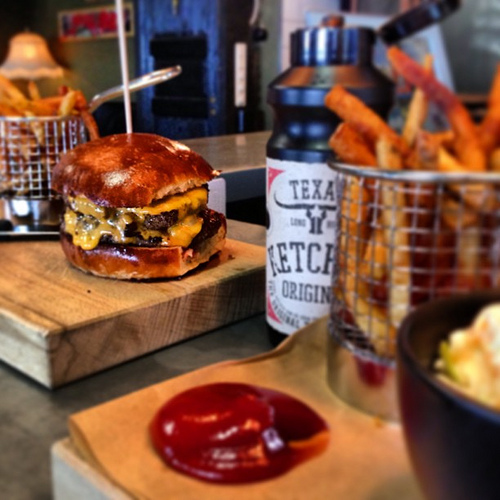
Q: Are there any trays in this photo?
A: No, there are no trays.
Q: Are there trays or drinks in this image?
A: No, there are no trays or drinks.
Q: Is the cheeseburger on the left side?
A: Yes, the cheeseburger is on the left of the image.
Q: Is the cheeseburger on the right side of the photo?
A: No, the cheeseburger is on the left of the image.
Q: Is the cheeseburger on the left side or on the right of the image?
A: The cheeseburger is on the left of the image.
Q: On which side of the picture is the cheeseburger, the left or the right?
A: The cheeseburger is on the left of the image.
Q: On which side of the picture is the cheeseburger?
A: The cheeseburger is on the left of the image.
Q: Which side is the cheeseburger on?
A: The cheeseburger is on the left of the image.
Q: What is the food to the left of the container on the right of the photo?
A: The food is a cheeseburger.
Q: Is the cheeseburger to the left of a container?
A: Yes, the cheeseburger is to the left of a container.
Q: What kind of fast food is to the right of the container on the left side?
A: The food is a cheeseburger.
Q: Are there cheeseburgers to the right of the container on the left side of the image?
A: Yes, there is a cheeseburger to the right of the container.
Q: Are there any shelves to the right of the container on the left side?
A: No, there is a cheeseburger to the right of the container.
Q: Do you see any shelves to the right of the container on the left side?
A: No, there is a cheeseburger to the right of the container.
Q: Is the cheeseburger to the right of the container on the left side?
A: Yes, the cheeseburger is to the right of the container.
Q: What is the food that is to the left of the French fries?
A: The food is a cheeseburger.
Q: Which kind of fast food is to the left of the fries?
A: The food is a cheeseburger.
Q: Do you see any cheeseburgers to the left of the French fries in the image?
A: Yes, there is a cheeseburger to the left of the French fries.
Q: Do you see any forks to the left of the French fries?
A: No, there is a cheeseburger to the left of the French fries.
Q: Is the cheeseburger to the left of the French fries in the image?
A: Yes, the cheeseburger is to the left of the French fries.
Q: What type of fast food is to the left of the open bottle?
A: The food is a cheeseburger.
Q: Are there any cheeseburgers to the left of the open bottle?
A: Yes, there is a cheeseburger to the left of the bottle.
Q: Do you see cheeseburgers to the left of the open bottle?
A: Yes, there is a cheeseburger to the left of the bottle.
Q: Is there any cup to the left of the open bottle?
A: No, there is a cheeseburger to the left of the bottle.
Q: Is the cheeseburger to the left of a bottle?
A: Yes, the cheeseburger is to the left of a bottle.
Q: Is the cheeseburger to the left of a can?
A: No, the cheeseburger is to the left of a bottle.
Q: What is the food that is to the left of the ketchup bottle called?
A: The food is a cheeseburger.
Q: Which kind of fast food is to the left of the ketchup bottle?
A: The food is a cheeseburger.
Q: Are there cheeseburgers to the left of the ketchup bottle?
A: Yes, there is a cheeseburger to the left of the ketchup bottle.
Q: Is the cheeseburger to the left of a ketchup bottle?
A: Yes, the cheeseburger is to the left of a ketchup bottle.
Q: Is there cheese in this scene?
A: Yes, there is cheese.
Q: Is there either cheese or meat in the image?
A: Yes, there is cheese.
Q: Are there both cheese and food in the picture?
A: Yes, there are both cheese and food.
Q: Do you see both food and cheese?
A: Yes, there are both cheese and food.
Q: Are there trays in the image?
A: No, there are no trays.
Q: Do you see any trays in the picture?
A: No, there are no trays.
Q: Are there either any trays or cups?
A: No, there are no trays or cups.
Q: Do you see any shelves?
A: No, there are no shelves.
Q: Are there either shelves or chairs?
A: No, there are no shelves or chairs.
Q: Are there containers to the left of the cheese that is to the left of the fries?
A: Yes, there is a container to the left of the cheese.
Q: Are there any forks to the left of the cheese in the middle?
A: No, there is a container to the left of the cheese.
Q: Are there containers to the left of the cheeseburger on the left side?
A: Yes, there is a container to the left of the cheeseburger.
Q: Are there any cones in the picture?
A: No, there are no cones.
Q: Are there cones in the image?
A: No, there are no cones.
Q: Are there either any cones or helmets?
A: No, there are no cones or helmets.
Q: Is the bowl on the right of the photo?
A: Yes, the bowl is on the right of the image.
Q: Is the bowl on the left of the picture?
A: No, the bowl is on the right of the image.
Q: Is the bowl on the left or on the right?
A: The bowl is on the right of the image.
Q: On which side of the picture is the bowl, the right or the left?
A: The bowl is on the right of the image.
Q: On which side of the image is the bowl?
A: The bowl is on the right of the image.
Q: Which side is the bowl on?
A: The bowl is on the right of the image.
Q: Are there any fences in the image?
A: No, there are no fences.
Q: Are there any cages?
A: No, there are no cages.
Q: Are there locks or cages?
A: No, there are no cages or locks.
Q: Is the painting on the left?
A: Yes, the painting is on the left of the image.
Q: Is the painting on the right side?
A: No, the painting is on the left of the image.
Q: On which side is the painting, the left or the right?
A: The painting is on the left of the image.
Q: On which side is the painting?
A: The painting is on the left of the image.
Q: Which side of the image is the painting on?
A: The painting is on the left of the image.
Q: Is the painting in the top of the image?
A: Yes, the painting is in the top of the image.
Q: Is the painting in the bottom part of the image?
A: No, the painting is in the top of the image.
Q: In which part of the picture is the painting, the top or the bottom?
A: The painting is in the top of the image.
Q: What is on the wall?
A: The painting is on the wall.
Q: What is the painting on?
A: The painting is on the wall.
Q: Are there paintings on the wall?
A: Yes, there is a painting on the wall.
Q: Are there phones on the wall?
A: No, there is a painting on the wall.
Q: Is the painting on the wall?
A: Yes, the painting is on the wall.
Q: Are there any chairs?
A: No, there are no chairs.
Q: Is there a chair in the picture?
A: No, there are no chairs.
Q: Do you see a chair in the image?
A: No, there are no chairs.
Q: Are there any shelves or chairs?
A: No, there are no chairs or shelves.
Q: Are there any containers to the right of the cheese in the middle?
A: Yes, there is a container to the right of the cheese.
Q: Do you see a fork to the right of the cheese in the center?
A: No, there is a container to the right of the cheese.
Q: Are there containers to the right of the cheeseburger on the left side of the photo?
A: Yes, there is a container to the right of the cheeseburger.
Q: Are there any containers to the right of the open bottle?
A: Yes, there is a container to the right of the bottle.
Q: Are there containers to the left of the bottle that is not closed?
A: No, the container is to the right of the bottle.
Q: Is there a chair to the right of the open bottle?
A: No, there is a container to the right of the bottle.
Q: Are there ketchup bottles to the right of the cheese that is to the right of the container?
A: Yes, there is a ketchup bottle to the right of the cheese.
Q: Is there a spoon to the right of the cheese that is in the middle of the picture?
A: No, there is a ketchup bottle to the right of the cheese.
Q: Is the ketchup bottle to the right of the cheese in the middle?
A: Yes, the ketchup bottle is to the right of the cheese.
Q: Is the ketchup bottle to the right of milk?
A: No, the ketchup bottle is to the right of the cheese.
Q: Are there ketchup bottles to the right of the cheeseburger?
A: Yes, there is a ketchup bottle to the right of the cheeseburger.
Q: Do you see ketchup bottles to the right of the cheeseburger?
A: Yes, there is a ketchup bottle to the right of the cheeseburger.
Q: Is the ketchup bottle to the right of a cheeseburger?
A: Yes, the ketchup bottle is to the right of a cheeseburger.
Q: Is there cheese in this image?
A: Yes, there is cheese.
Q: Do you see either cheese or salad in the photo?
A: Yes, there is cheese.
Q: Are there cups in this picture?
A: No, there are no cups.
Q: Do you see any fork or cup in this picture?
A: No, there are no cups or forks.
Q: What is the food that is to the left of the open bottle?
A: The food is cheese.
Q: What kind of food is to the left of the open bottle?
A: The food is cheese.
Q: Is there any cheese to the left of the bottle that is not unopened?
A: Yes, there is cheese to the left of the bottle.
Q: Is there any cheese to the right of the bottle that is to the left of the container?
A: No, the cheese is to the left of the bottle.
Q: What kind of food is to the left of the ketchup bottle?
A: The food is cheese.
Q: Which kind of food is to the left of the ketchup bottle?
A: The food is cheese.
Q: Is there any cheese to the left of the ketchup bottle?
A: Yes, there is cheese to the left of the ketchup bottle.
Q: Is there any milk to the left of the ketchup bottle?
A: No, there is cheese to the left of the ketchup bottle.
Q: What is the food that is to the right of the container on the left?
A: The food is cheese.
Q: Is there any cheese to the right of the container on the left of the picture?
A: Yes, there is cheese to the right of the container.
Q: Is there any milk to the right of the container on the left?
A: No, there is cheese to the right of the container.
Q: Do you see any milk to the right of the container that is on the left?
A: No, there is cheese to the right of the container.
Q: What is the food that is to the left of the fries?
A: The food is cheese.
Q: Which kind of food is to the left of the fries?
A: The food is cheese.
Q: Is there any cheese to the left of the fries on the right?
A: Yes, there is cheese to the left of the fries.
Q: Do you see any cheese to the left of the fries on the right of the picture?
A: Yes, there is cheese to the left of the fries.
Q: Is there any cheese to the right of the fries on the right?
A: No, the cheese is to the left of the French fries.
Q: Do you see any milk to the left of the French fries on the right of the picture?
A: No, there is cheese to the left of the French fries.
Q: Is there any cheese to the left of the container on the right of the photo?
A: Yes, there is cheese to the left of the container.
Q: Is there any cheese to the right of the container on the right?
A: No, the cheese is to the left of the container.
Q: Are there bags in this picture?
A: Yes, there is a bag.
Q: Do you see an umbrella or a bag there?
A: Yes, there is a bag.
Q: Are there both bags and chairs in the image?
A: No, there is a bag but no chairs.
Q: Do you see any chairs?
A: No, there are no chairs.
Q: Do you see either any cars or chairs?
A: No, there are no chairs or cars.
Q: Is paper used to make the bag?
A: Yes, the bag is made of paper.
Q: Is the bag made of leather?
A: No, the bag is made of paper.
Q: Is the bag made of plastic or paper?
A: The bag is made of paper.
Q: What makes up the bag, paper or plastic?
A: The bag is made of paper.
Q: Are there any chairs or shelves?
A: No, there are no chairs or shelves.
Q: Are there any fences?
A: No, there are no fences.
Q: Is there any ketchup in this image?
A: Yes, there is ketchup.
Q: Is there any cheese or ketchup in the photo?
A: Yes, there is ketchup.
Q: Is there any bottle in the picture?
A: Yes, there is a bottle.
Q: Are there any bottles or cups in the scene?
A: Yes, there is a bottle.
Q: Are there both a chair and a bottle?
A: No, there is a bottle but no chairs.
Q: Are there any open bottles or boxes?
A: Yes, there is an open bottle.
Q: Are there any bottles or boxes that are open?
A: Yes, the bottle is open.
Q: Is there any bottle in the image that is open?
A: Yes, there is an open bottle.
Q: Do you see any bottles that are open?
A: Yes, there is a bottle that is open.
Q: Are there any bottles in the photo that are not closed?
A: Yes, there is a open bottle.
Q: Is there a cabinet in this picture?
A: No, there are no cabinets.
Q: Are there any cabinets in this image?
A: No, there are no cabinets.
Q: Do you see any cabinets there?
A: No, there are no cabinets.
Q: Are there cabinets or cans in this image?
A: No, there are no cabinets or cans.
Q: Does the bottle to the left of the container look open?
A: Yes, the bottle is open.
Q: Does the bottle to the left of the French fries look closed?
A: No, the bottle is open.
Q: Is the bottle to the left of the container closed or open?
A: The bottle is open.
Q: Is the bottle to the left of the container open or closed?
A: The bottle is open.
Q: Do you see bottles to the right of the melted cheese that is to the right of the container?
A: Yes, there is a bottle to the right of the cheese.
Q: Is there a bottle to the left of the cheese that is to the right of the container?
A: No, the bottle is to the right of the cheese.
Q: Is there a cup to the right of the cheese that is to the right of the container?
A: No, there is a bottle to the right of the cheese.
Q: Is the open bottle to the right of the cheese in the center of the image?
A: Yes, the bottle is to the right of the cheese.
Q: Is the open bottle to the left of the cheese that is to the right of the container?
A: No, the bottle is to the right of the cheese.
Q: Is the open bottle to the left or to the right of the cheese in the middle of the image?
A: The bottle is to the right of the cheese.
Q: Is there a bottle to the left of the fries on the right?
A: Yes, there is a bottle to the left of the fries.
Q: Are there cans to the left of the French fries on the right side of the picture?
A: No, there is a bottle to the left of the fries.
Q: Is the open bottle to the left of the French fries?
A: Yes, the bottle is to the left of the French fries.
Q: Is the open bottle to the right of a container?
A: No, the bottle is to the left of a container.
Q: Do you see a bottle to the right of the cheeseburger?
A: Yes, there is a bottle to the right of the cheeseburger.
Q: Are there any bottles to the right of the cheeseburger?
A: Yes, there is a bottle to the right of the cheeseburger.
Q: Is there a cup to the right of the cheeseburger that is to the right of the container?
A: No, there is a bottle to the right of the cheeseburger.